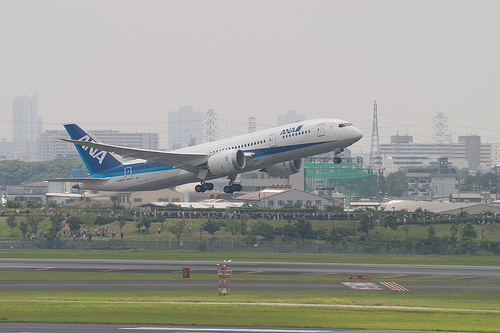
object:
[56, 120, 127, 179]
tail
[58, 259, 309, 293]
runway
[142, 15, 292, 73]
sky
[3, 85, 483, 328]
airport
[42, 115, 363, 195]
jet plane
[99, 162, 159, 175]
stripe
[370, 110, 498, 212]
buildings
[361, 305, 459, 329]
grass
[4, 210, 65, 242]
trees